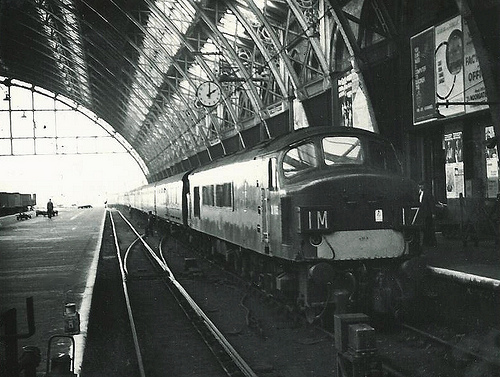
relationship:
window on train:
[282, 140, 319, 177] [106, 125, 428, 323]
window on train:
[322, 135, 365, 165] [106, 125, 428, 323]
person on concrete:
[46, 197, 54, 218] [2, 212, 100, 337]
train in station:
[106, 125, 428, 323] [0, 11, 498, 375]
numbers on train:
[399, 205, 421, 225] [106, 125, 428, 323]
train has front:
[106, 125, 428, 323] [272, 124, 436, 311]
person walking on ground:
[46, 195, 55, 220] [6, 205, 108, 375]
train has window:
[106, 125, 428, 323] [284, 129, 401, 179]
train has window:
[106, 125, 428, 323] [197, 182, 216, 210]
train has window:
[106, 125, 428, 323] [212, 181, 237, 210]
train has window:
[106, 125, 428, 323] [277, 137, 318, 179]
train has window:
[106, 125, 428, 323] [318, 128, 366, 177]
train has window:
[106, 125, 428, 323] [364, 133, 403, 177]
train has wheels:
[129, 125, 449, 336] [216, 236, 311, 332]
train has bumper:
[106, 125, 428, 323] [302, 228, 432, 315]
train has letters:
[106, 125, 428, 323] [307, 206, 327, 231]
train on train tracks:
[106, 125, 428, 323] [109, 209, 147, 375]